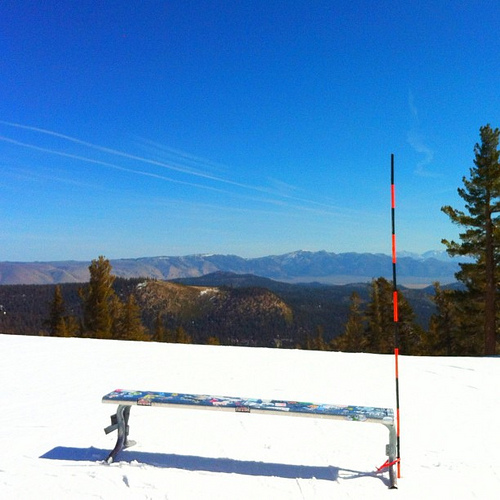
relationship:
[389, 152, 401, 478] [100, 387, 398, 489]
pole attached to bench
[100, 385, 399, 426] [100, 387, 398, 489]
stickers on bench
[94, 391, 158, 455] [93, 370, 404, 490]
legs on bench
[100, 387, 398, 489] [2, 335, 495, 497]
bench on top of snow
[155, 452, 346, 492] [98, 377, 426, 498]
shadow of bench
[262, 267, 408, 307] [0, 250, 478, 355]
trees on mountain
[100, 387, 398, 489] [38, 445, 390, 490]
bench with shadow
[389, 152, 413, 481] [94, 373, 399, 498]
pole attached to bench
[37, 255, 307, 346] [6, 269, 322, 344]
tree covered mountain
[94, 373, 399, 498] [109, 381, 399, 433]
bench with seat